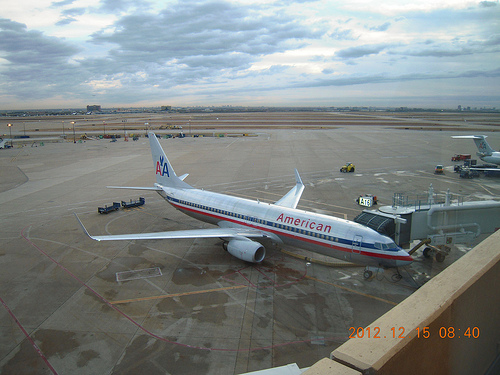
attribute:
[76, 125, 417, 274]
jet — intercontinental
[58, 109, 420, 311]
airplane — silver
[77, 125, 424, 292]
airplane — white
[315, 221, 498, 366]
wall — brown, tan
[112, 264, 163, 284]
square — white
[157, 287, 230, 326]
spots — wet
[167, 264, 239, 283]
spots — wet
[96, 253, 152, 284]
spots — wet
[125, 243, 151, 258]
spots — wet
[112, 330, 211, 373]
spots — wet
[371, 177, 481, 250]
building — small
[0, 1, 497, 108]
clouds — dark, fluffy, dreary